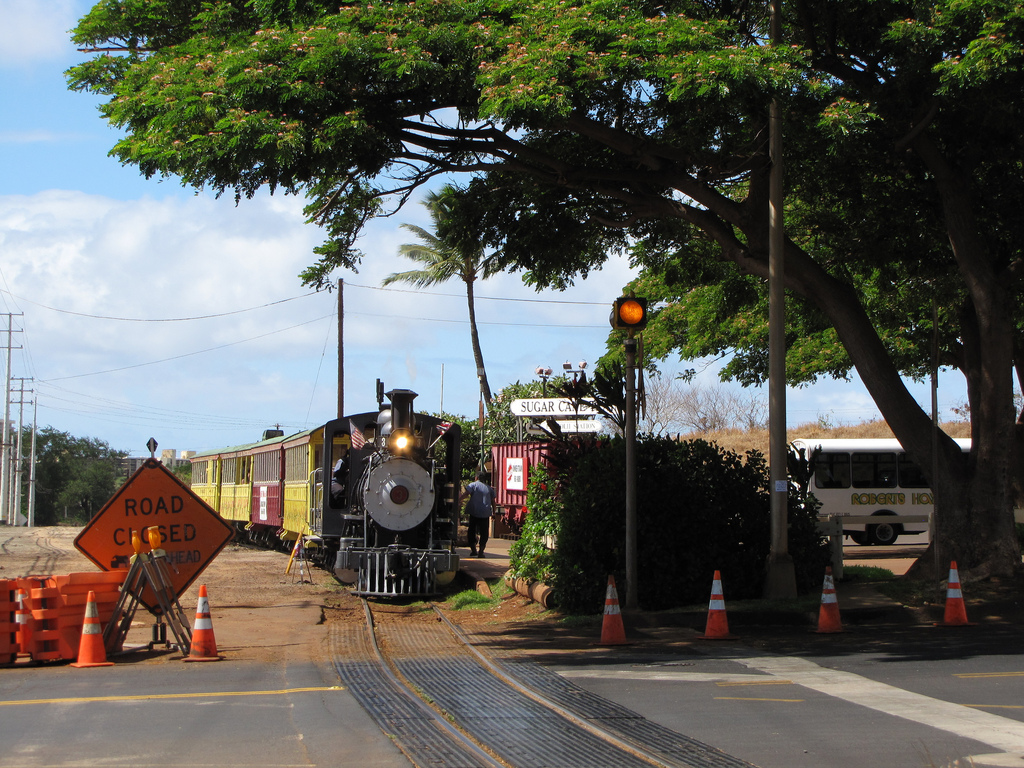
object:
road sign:
[76, 461, 234, 616]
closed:
[112, 522, 200, 547]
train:
[189, 381, 465, 604]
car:
[190, 447, 225, 513]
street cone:
[184, 586, 225, 662]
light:
[614, 299, 649, 330]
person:
[458, 471, 499, 559]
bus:
[788, 436, 977, 546]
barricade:
[0, 566, 129, 666]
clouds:
[0, 193, 154, 288]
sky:
[0, 0, 617, 436]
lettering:
[110, 496, 200, 566]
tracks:
[361, 597, 506, 767]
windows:
[851, 451, 898, 490]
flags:
[348, 421, 368, 451]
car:
[250, 430, 283, 530]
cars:
[216, 440, 254, 524]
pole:
[763, 0, 794, 609]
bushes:
[507, 432, 623, 602]